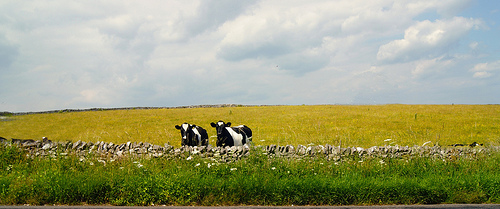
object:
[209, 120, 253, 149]
cow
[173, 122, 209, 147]
cow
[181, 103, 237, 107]
wall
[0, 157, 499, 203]
grass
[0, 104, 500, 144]
field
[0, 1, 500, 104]
sky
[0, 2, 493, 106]
cloud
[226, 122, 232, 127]
ear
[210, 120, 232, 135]
head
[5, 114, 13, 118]
trees